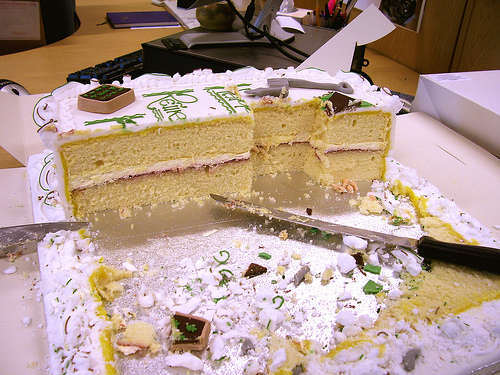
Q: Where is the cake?
A: On tray.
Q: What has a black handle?
A: Knife.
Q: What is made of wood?
A: Table.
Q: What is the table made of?
A: Wood.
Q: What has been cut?
A: Cake.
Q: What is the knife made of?
A: Metal.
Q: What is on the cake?
A: Frosting.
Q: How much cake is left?
A: Less than half.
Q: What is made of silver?
A: Knife blade.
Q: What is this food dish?
A: Cake.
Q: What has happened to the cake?
A: Been cut.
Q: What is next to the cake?
A: Knife.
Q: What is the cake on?
A: A tray.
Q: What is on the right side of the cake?
A: A box.